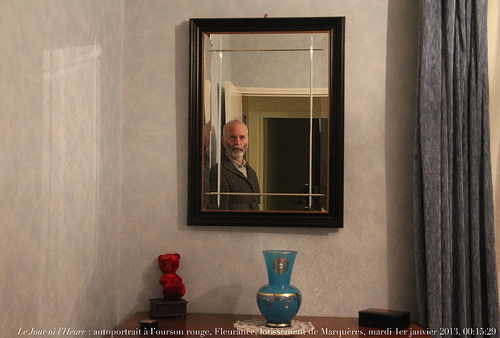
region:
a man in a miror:
[208, 118, 259, 209]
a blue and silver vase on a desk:
[256, 246, 299, 324]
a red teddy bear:
[156, 250, 182, 295]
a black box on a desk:
[357, 307, 407, 327]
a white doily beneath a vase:
[231, 317, 311, 335]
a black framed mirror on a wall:
[188, 16, 345, 230]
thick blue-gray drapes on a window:
[416, 0, 498, 336]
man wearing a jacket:
[211, 156, 260, 212]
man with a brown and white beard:
[222, 118, 248, 163]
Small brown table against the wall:
[99, 311, 433, 336]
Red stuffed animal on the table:
[156, 251, 187, 296]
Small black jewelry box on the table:
[356, 305, 412, 335]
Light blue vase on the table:
[256, 247, 303, 325]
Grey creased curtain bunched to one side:
[419, 0, 498, 328]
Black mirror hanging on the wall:
[186, 18, 344, 231]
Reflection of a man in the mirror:
[208, 121, 260, 208]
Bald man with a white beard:
[223, 120, 255, 164]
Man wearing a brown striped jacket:
[201, 160, 264, 209]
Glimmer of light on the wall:
[28, 39, 108, 330]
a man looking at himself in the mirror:
[208, 115, 267, 205]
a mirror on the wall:
[156, 8, 386, 240]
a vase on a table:
[244, 233, 321, 334]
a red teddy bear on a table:
[138, 252, 199, 321]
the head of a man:
[218, 118, 253, 161]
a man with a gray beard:
[211, 115, 253, 164]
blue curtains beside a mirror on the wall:
[419, 0, 491, 332]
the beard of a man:
[223, 141, 251, 160]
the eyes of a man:
[226, 131, 248, 141]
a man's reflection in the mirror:
[207, 118, 261, 207]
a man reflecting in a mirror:
[208, 120, 260, 210]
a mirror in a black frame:
[204, 32, 328, 208]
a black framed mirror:
[186, 16, 345, 226]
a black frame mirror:
[186, 17, 347, 226]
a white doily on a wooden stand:
[233, 317, 314, 336]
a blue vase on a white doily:
[235, 248, 315, 335]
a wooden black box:
[356, 306, 407, 328]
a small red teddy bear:
[157, 252, 187, 298]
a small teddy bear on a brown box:
[147, 252, 189, 319]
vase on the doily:
[235, 236, 305, 326]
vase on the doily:
[236, 240, 305, 322]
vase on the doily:
[236, 245, 308, 328]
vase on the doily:
[235, 239, 309, 334]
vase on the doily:
[240, 238, 299, 327]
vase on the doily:
[247, 240, 309, 328]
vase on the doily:
[236, 233, 301, 332]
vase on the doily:
[253, 241, 307, 328]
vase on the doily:
[251, 241, 303, 319]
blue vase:
[229, 236, 309, 328]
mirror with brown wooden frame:
[182, 8, 348, 228]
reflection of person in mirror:
[211, 117, 256, 207]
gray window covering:
[413, 33, 489, 296]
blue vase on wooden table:
[242, 232, 308, 326]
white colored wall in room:
[56, 249, 87, 284]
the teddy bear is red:
[160, 254, 184, 300]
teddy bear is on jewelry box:
[147, 251, 191, 321]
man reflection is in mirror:
[220, 117, 267, 212]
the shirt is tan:
[235, 160, 249, 177]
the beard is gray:
[234, 144, 245, 160]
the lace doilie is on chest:
[237, 311, 314, 336]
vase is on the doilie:
[257, 245, 307, 336]